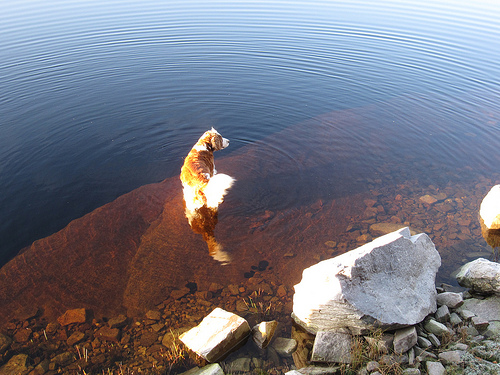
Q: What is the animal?
A: Dog.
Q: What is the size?
A: Large.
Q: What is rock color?
A: White.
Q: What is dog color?
A: Brown.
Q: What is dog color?
A: White.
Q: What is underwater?
A: Ledge.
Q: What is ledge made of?
A: Rock.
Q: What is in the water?
A: Ripples.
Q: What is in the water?
A: Rocks.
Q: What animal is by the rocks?
A: Dog swimming.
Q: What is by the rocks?
A: Dog in water.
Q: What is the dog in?
A: Clean and clear water.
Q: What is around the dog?
A: Ripples of water.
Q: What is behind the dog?
A: Stone on shore.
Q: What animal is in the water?
A: Brown and white dog.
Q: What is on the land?
A: Stones, big and small.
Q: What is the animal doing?
A: Dog is swimming.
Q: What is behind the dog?
A: Rock.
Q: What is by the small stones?
A: Big rock.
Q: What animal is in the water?
A: Dog.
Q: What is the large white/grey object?
A: Rock.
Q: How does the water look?
A: Calm.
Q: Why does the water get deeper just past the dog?
A: Drop off.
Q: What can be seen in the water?
A: Rocks.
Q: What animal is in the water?
A: Dog.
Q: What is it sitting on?
A: Rock.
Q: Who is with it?
A: No one.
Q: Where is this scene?
A: At a lake.